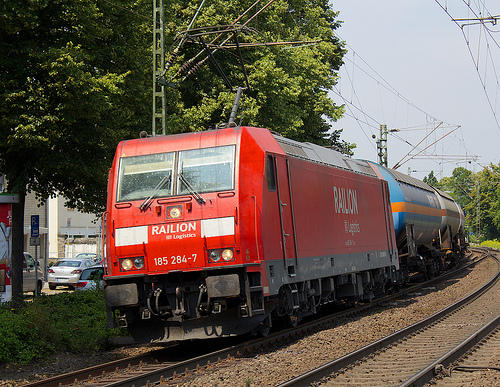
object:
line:
[432, 3, 498, 135]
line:
[339, 12, 470, 128]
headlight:
[222, 249, 234, 261]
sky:
[366, 5, 438, 62]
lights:
[210, 251, 221, 262]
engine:
[102, 126, 402, 345]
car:
[74, 253, 100, 265]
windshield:
[117, 144, 236, 202]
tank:
[354, 158, 442, 248]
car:
[47, 258, 96, 290]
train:
[102, 125, 470, 347]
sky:
[451, 116, 499, 179]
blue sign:
[31, 215, 39, 237]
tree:
[0, 2, 354, 312]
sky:
[351, 29, 433, 107]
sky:
[425, 9, 498, 83]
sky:
[338, 15, 387, 64]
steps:
[275, 155, 300, 270]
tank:
[429, 185, 460, 244]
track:
[438, 246, 500, 333]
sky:
[317, 124, 387, 158]